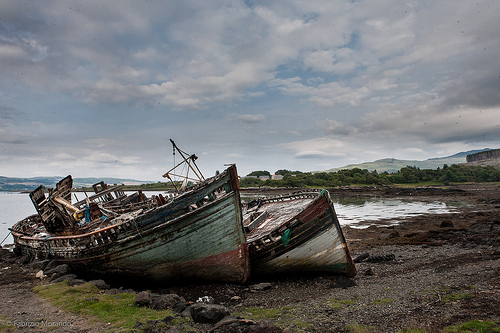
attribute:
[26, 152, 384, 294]
wreckage — ship, old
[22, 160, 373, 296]
boats — old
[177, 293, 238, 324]
rock — black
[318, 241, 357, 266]
mark — white